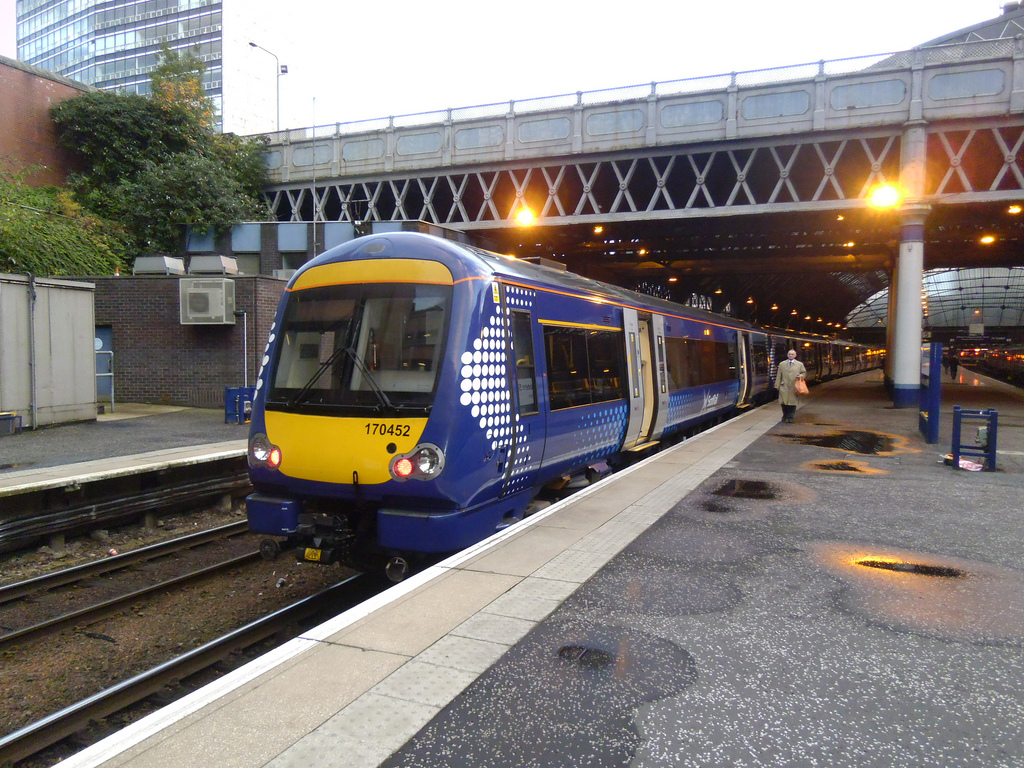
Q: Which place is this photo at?
A: It is at the sidewalk.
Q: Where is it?
A: This is at the sidewalk.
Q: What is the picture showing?
A: It is showing a sidewalk.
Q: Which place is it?
A: It is a sidewalk.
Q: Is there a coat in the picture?
A: Yes, there is a coat.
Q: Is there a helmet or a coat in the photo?
A: Yes, there is a coat.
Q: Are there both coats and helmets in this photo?
A: No, there is a coat but no helmets.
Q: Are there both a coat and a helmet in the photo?
A: No, there is a coat but no helmets.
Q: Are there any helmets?
A: No, there are no helmets.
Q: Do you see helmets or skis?
A: No, there are no helmets or skis.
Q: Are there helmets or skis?
A: No, there are no helmets or skis.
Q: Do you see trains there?
A: Yes, there is a train.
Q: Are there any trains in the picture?
A: Yes, there is a train.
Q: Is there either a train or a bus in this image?
A: Yes, there is a train.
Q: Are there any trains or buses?
A: Yes, there is a train.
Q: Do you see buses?
A: No, there are no buses.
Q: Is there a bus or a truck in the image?
A: No, there are no buses or trucks.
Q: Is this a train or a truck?
A: This is a train.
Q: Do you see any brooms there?
A: No, there are no brooms.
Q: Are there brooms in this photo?
A: No, there are no brooms.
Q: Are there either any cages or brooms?
A: No, there are no brooms or cages.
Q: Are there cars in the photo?
A: No, there are no cars.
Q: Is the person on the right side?
A: Yes, the person is on the right of the image.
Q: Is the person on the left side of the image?
A: No, the person is on the right of the image.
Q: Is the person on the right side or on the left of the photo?
A: The person is on the right of the image.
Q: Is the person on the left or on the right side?
A: The person is on the right of the image.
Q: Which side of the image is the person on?
A: The person is on the right of the image.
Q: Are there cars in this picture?
A: No, there are no cars.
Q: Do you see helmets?
A: No, there are no helmets.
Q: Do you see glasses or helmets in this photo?
A: No, there are no helmets or glasses.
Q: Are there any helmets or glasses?
A: No, there are no helmets or glasses.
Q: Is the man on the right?
A: Yes, the man is on the right of the image.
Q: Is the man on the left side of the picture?
A: No, the man is on the right of the image.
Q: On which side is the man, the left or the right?
A: The man is on the right of the image.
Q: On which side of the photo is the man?
A: The man is on the right of the image.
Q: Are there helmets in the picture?
A: No, there are no helmets.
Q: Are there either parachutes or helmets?
A: No, there are no helmets or parachutes.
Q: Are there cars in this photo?
A: No, there are no cars.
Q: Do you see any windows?
A: Yes, there is a window.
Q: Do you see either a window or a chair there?
A: Yes, there is a window.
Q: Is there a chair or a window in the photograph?
A: Yes, there is a window.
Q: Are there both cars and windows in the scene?
A: No, there is a window but no cars.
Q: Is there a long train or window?
A: Yes, there is a long window.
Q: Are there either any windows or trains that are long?
A: Yes, the window is long.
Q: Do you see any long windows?
A: Yes, there is a long window.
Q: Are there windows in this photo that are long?
A: Yes, there is a window that is long.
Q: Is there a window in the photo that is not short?
A: Yes, there is a long window.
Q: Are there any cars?
A: No, there are no cars.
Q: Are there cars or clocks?
A: No, there are no cars or clocks.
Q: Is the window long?
A: Yes, the window is long.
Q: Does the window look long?
A: Yes, the window is long.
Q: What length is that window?
A: The window is long.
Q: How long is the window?
A: The window is long.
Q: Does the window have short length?
A: No, the window is long.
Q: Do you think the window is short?
A: No, the window is long.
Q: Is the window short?
A: No, the window is long.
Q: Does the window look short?
A: No, the window is long.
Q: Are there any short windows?
A: No, there is a window but it is long.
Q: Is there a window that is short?
A: No, there is a window but it is long.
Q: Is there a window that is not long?
A: No, there is a window but it is long.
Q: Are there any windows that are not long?
A: No, there is a window but it is long.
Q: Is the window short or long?
A: The window is long.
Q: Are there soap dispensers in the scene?
A: No, there are no soap dispensers.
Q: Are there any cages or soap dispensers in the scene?
A: No, there are no soap dispensers or cages.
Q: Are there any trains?
A: Yes, there is a train.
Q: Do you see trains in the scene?
A: Yes, there is a train.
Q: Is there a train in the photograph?
A: Yes, there is a train.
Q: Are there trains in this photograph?
A: Yes, there is a train.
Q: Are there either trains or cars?
A: Yes, there is a train.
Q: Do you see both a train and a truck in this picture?
A: No, there is a train but no trucks.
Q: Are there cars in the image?
A: No, there are no cars.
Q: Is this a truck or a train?
A: This is a train.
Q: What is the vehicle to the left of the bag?
A: The vehicle is a train.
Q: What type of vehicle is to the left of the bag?
A: The vehicle is a train.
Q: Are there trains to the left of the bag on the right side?
A: Yes, there is a train to the left of the bag.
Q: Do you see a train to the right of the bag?
A: No, the train is to the left of the bag.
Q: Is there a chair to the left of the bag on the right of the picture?
A: No, there is a train to the left of the bag.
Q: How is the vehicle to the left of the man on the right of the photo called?
A: The vehicle is a train.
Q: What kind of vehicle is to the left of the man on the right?
A: The vehicle is a train.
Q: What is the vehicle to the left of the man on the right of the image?
A: The vehicle is a train.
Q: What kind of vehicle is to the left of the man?
A: The vehicle is a train.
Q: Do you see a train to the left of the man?
A: Yes, there is a train to the left of the man.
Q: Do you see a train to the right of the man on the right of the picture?
A: No, the train is to the left of the man.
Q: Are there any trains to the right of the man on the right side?
A: No, the train is to the left of the man.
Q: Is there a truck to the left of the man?
A: No, there is a train to the left of the man.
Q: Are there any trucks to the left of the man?
A: No, there is a train to the left of the man.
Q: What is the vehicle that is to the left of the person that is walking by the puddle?
A: The vehicle is a train.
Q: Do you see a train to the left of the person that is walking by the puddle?
A: Yes, there is a train to the left of the person.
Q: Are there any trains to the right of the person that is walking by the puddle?
A: No, the train is to the left of the person.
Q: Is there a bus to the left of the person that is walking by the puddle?
A: No, there is a train to the left of the person.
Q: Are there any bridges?
A: Yes, there is a bridge.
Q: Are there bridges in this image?
A: Yes, there is a bridge.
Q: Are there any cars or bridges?
A: Yes, there is a bridge.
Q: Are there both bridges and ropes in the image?
A: No, there is a bridge but no ropes.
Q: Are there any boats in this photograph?
A: No, there are no boats.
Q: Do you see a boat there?
A: No, there are no boats.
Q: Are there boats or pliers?
A: No, there are no boats or pliers.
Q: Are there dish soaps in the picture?
A: No, there are no dish soaps.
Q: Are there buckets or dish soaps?
A: No, there are no dish soaps or buckets.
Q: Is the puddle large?
A: Yes, the puddle is large.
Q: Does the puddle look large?
A: Yes, the puddle is large.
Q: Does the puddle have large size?
A: Yes, the puddle is large.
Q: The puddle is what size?
A: The puddle is large.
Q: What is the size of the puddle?
A: The puddle is large.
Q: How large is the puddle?
A: The puddle is large.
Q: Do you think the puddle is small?
A: No, the puddle is large.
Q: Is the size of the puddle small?
A: No, the puddle is large.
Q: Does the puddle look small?
A: No, the puddle is large.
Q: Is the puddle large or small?
A: The puddle is large.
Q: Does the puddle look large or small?
A: The puddle is large.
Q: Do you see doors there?
A: Yes, there are doors.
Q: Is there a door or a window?
A: Yes, there are doors.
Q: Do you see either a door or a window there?
A: Yes, there are doors.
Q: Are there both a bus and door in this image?
A: No, there are doors but no buses.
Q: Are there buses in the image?
A: No, there are no buses.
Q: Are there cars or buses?
A: No, there are no buses or cars.